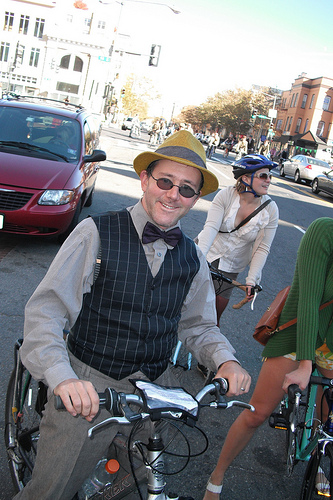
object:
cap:
[105, 459, 120, 474]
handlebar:
[223, 377, 229, 393]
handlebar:
[52, 392, 106, 410]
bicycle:
[169, 258, 264, 371]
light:
[250, 88, 255, 92]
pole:
[268, 95, 276, 129]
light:
[251, 115, 271, 120]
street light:
[252, 115, 256, 119]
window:
[309, 94, 315, 108]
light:
[152, 46, 160, 66]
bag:
[252, 286, 333, 346]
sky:
[172, 0, 333, 121]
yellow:
[183, 134, 200, 145]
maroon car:
[0, 98, 105, 235]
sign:
[98, 55, 111, 63]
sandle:
[205, 482, 222, 493]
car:
[310, 170, 333, 195]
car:
[0, 100, 107, 236]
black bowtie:
[142, 221, 181, 248]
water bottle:
[66, 440, 134, 499]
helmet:
[230, 154, 278, 180]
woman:
[196, 152, 279, 329]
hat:
[132, 128, 220, 196]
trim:
[151, 146, 208, 169]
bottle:
[71, 458, 120, 500]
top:
[105, 458, 121, 474]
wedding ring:
[240, 387, 245, 390]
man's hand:
[212, 359, 252, 397]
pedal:
[269, 411, 289, 430]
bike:
[269, 363, 333, 500]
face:
[152, 160, 201, 227]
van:
[25, 98, 73, 200]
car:
[279, 154, 333, 182]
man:
[16, 128, 252, 500]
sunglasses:
[150, 170, 199, 198]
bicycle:
[0, 337, 255, 500]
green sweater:
[261, 215, 333, 363]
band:
[154, 145, 208, 169]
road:
[0, 123, 333, 500]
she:
[202, 216, 333, 500]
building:
[273, 71, 333, 163]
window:
[83, 120, 93, 154]